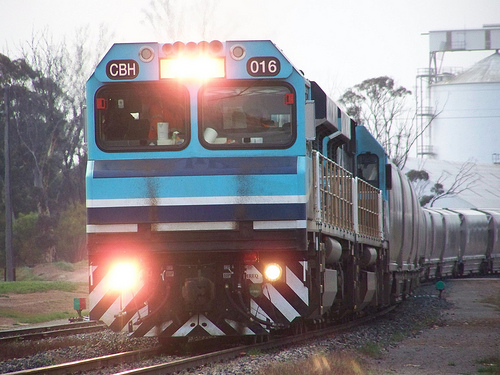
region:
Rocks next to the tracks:
[350, 296, 452, 346]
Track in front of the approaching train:
[15, 351, 247, 373]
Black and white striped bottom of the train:
[88, 266, 311, 337]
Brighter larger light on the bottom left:
[105, 255, 150, 295]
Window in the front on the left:
[92, 83, 189, 155]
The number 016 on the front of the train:
[246, 52, 283, 77]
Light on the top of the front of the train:
[156, 58, 229, 85]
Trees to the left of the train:
[1, 55, 86, 231]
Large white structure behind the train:
[411, 18, 499, 199]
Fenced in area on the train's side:
[312, 149, 392, 244]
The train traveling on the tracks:
[71, 30, 499, 341]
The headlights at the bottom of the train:
[87, 235, 291, 302]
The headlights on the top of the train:
[161, 47, 225, 91]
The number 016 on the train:
[247, 54, 284, 79]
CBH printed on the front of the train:
[101, 58, 146, 87]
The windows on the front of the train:
[94, 72, 305, 169]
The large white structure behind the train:
[408, 20, 499, 228]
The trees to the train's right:
[0, 22, 104, 273]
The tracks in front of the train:
[11, 333, 266, 373]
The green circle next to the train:
[432, 277, 450, 304]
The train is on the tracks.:
[60, 35, 423, 364]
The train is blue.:
[75, 31, 328, 256]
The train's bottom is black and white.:
[62, 247, 394, 349]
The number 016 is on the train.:
[239, 50, 292, 82]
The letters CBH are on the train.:
[90, 48, 144, 88]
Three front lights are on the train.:
[91, 52, 294, 302]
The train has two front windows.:
[79, 70, 301, 160]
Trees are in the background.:
[0, 28, 110, 264]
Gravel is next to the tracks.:
[166, 288, 445, 373]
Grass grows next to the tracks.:
[0, 266, 80, 319]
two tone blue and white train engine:
[85, 35, 360, 340]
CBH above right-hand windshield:
[87, 41, 194, 160]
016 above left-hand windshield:
[206, 53, 301, 157]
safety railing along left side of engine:
[305, 142, 391, 258]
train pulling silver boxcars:
[81, 38, 498, 343]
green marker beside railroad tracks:
[421, 273, 457, 305]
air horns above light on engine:
[148, 38, 234, 56]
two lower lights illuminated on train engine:
[90, 248, 297, 334]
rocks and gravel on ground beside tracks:
[373, 293, 450, 342]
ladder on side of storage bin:
[415, 65, 462, 161]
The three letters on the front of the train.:
[105, 58, 145, 81]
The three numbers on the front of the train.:
[245, 57, 280, 77]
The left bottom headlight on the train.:
[95, 235, 147, 292]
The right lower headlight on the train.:
[264, 256, 285, 283]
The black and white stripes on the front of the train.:
[87, 257, 308, 342]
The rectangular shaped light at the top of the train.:
[152, 60, 234, 81]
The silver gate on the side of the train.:
[307, 145, 392, 238]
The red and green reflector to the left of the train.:
[66, 298, 90, 315]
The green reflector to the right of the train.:
[432, 279, 447, 292]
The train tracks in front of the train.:
[5, 328, 250, 372]